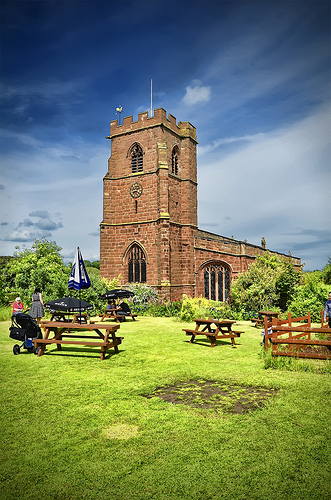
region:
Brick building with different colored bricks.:
[81, 79, 313, 313]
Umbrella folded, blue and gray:
[57, 240, 89, 294]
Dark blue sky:
[5, 0, 321, 240]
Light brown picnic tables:
[34, 295, 238, 381]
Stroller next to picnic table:
[4, 306, 40, 359]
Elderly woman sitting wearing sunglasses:
[10, 289, 19, 310]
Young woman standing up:
[23, 280, 53, 320]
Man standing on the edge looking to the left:
[309, 289, 330, 344]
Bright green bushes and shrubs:
[241, 238, 317, 317]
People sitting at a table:
[103, 291, 131, 318]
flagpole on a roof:
[144, 75, 160, 119]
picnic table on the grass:
[177, 312, 246, 352]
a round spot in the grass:
[94, 414, 147, 450]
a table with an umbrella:
[96, 279, 136, 324]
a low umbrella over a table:
[44, 291, 94, 321]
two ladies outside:
[8, 285, 51, 324]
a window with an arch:
[193, 256, 237, 308]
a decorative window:
[118, 236, 152, 285]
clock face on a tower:
[123, 181, 147, 207]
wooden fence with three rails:
[257, 309, 328, 369]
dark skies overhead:
[34, 31, 136, 76]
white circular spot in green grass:
[102, 411, 158, 448]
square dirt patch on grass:
[146, 367, 278, 437]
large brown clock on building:
[118, 175, 153, 199]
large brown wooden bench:
[179, 307, 253, 357]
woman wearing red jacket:
[6, 294, 54, 320]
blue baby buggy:
[8, 309, 64, 373]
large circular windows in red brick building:
[194, 251, 254, 323]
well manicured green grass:
[37, 380, 103, 422]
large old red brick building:
[83, 79, 304, 384]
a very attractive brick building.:
[48, 51, 307, 336]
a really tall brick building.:
[36, 64, 308, 342]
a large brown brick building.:
[59, 70, 299, 368]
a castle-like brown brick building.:
[67, 53, 289, 362]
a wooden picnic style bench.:
[183, 312, 238, 354]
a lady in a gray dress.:
[24, 278, 44, 316]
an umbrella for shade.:
[56, 236, 90, 312]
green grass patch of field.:
[15, 405, 242, 480]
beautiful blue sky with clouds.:
[167, 19, 304, 107]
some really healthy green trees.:
[8, 242, 62, 286]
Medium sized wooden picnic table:
[168, 308, 250, 354]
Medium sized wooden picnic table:
[26, 319, 133, 360]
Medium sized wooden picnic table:
[248, 303, 287, 331]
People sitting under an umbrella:
[94, 280, 149, 324]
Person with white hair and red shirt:
[7, 292, 28, 325]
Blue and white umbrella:
[66, 243, 97, 321]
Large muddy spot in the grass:
[141, 370, 292, 425]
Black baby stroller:
[3, 306, 54, 363]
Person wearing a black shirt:
[113, 297, 136, 319]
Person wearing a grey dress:
[27, 283, 50, 324]